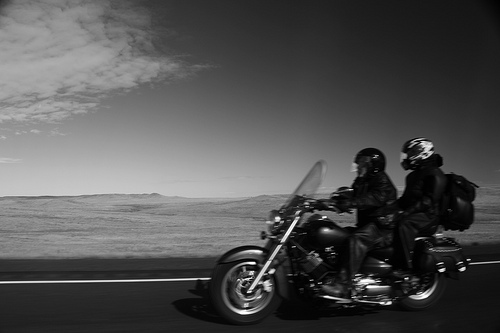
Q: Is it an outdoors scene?
A: Yes, it is outdoors.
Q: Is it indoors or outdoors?
A: It is outdoors.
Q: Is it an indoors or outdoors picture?
A: It is outdoors.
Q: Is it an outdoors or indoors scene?
A: It is outdoors.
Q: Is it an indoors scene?
A: No, it is outdoors.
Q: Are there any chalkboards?
A: No, there are no chalkboards.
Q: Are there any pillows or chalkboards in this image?
A: No, there are no chalkboards or pillows.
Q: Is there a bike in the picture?
A: Yes, there is a bike.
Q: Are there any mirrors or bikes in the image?
A: Yes, there is a bike.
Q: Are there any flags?
A: No, there are no flags.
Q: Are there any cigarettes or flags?
A: No, there are no flags or cigarettes.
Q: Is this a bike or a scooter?
A: This is a bike.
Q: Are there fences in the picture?
A: No, there are no fences.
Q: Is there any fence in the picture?
A: No, there are no fences.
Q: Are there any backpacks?
A: Yes, there is a backpack.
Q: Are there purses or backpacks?
A: Yes, there is a backpack.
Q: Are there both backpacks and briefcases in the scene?
A: No, there is a backpack but no briefcases.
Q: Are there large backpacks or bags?
A: Yes, there is a large backpack.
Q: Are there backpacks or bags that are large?
A: Yes, the backpack is large.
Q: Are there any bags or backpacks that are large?
A: Yes, the backpack is large.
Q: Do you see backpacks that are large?
A: Yes, there is a large backpack.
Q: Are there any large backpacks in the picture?
A: Yes, there is a large backpack.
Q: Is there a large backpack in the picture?
A: Yes, there is a large backpack.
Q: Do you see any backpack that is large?
A: Yes, there is a backpack that is large.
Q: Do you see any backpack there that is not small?
A: Yes, there is a large backpack.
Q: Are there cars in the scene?
A: No, there are no cars.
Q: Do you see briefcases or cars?
A: No, there are no cars or briefcases.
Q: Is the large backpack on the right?
A: Yes, the backpack is on the right of the image.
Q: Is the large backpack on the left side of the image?
A: No, the backpack is on the right of the image.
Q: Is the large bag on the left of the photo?
A: No, the backpack is on the right of the image.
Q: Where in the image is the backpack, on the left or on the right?
A: The backpack is on the right of the image.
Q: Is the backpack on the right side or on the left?
A: The backpack is on the right of the image.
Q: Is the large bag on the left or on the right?
A: The backpack is on the right of the image.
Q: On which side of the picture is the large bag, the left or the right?
A: The backpack is on the right of the image.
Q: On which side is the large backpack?
A: The backpack is on the right of the image.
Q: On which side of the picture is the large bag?
A: The backpack is on the right of the image.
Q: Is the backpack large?
A: Yes, the backpack is large.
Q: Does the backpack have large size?
A: Yes, the backpack is large.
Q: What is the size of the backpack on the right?
A: The backpack is large.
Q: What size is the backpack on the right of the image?
A: The backpack is large.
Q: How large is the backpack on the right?
A: The backpack is large.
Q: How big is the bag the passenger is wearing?
A: The backpack is large.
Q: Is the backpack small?
A: No, the backpack is large.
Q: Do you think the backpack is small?
A: No, the backpack is large.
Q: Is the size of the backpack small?
A: No, the backpack is large.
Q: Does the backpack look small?
A: No, the backpack is large.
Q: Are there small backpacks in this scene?
A: No, there is a backpack but it is large.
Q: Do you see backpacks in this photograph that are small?
A: No, there is a backpack but it is large.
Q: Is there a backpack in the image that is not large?
A: No, there is a backpack but it is large.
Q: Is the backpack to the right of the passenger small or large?
A: The backpack is large.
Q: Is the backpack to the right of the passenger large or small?
A: The backpack is large.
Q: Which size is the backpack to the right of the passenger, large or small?
A: The backpack is large.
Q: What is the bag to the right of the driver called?
A: The bag is a backpack.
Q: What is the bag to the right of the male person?
A: The bag is a backpack.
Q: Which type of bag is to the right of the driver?
A: The bag is a backpack.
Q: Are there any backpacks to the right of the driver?
A: Yes, there is a backpack to the right of the driver.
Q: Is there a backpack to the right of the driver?
A: Yes, there is a backpack to the right of the driver.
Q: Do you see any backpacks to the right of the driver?
A: Yes, there is a backpack to the right of the driver.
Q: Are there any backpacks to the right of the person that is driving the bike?
A: Yes, there is a backpack to the right of the driver.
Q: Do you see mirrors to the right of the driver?
A: No, there is a backpack to the right of the driver.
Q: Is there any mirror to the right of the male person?
A: No, there is a backpack to the right of the driver.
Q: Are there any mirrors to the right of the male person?
A: No, there is a backpack to the right of the driver.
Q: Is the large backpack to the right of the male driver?
A: Yes, the backpack is to the right of the driver.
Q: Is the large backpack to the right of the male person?
A: Yes, the backpack is to the right of the driver.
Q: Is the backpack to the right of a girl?
A: No, the backpack is to the right of the driver.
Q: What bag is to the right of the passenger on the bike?
A: The bag is a backpack.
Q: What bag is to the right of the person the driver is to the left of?
A: The bag is a backpack.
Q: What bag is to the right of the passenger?
A: The bag is a backpack.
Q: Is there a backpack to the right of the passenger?
A: Yes, there is a backpack to the right of the passenger.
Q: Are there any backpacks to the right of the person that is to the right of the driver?
A: Yes, there is a backpack to the right of the passenger.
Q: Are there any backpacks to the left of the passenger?
A: No, the backpack is to the right of the passenger.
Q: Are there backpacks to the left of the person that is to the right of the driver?
A: No, the backpack is to the right of the passenger.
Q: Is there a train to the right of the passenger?
A: No, there is a backpack to the right of the passenger.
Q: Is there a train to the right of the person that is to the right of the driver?
A: No, there is a backpack to the right of the passenger.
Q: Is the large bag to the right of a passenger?
A: Yes, the backpack is to the right of a passenger.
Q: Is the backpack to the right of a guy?
A: No, the backpack is to the right of a passenger.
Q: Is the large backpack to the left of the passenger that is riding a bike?
A: No, the backpack is to the right of the passenger.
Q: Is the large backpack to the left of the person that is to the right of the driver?
A: No, the backpack is to the right of the passenger.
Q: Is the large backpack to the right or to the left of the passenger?
A: The backpack is to the right of the passenger.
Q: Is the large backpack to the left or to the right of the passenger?
A: The backpack is to the right of the passenger.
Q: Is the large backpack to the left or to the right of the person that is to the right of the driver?
A: The backpack is to the right of the passenger.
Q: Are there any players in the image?
A: No, there are no players.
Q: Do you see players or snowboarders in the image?
A: No, there are no players or snowboarders.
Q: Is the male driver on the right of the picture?
A: Yes, the driver is on the right of the image.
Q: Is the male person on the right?
A: Yes, the driver is on the right of the image.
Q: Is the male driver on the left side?
A: No, the driver is on the right of the image.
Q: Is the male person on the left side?
A: No, the driver is on the right of the image.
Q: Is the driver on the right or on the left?
A: The driver is on the right of the image.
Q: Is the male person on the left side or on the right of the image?
A: The driver is on the right of the image.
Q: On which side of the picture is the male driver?
A: The driver is on the right of the image.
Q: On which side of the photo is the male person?
A: The driver is on the right of the image.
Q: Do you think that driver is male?
A: Yes, the driver is male.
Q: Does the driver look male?
A: Yes, the driver is male.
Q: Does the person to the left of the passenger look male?
A: Yes, the driver is male.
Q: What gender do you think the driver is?
A: The driver is male.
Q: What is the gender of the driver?
A: The driver is male.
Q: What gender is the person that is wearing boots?
A: The driver is male.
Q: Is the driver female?
A: No, the driver is male.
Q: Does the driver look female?
A: No, the driver is male.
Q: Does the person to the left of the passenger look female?
A: No, the driver is male.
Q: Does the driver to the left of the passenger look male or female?
A: The driver is male.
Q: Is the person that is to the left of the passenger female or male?
A: The driver is male.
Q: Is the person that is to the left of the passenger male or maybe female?
A: The driver is male.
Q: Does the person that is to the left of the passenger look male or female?
A: The driver is male.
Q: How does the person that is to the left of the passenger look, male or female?
A: The driver is male.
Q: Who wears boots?
A: The driver wears boots.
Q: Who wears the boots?
A: The driver wears boots.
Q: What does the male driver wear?
A: The driver wears boots.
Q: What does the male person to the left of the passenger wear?
A: The driver wears boots.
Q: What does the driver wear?
A: The driver wears boots.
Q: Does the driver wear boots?
A: Yes, the driver wears boots.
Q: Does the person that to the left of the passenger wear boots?
A: Yes, the driver wears boots.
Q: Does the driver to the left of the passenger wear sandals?
A: No, the driver wears boots.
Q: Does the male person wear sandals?
A: No, the driver wears boots.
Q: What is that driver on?
A: The driver is on the bike.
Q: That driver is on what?
A: The driver is on the bike.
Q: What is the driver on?
A: The driver is on the bike.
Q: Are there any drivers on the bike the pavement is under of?
A: Yes, there is a driver on the bike.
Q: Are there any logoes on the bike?
A: No, there is a driver on the bike.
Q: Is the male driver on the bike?
A: Yes, the driver is on the bike.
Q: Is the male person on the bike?
A: Yes, the driver is on the bike.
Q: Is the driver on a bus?
A: No, the driver is on the bike.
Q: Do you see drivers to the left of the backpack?
A: Yes, there is a driver to the left of the backpack.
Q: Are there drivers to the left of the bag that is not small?
A: Yes, there is a driver to the left of the backpack.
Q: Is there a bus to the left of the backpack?
A: No, there is a driver to the left of the backpack.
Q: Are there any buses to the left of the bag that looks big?
A: No, there is a driver to the left of the backpack.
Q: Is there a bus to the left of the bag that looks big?
A: No, there is a driver to the left of the backpack.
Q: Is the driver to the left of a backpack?
A: Yes, the driver is to the left of a backpack.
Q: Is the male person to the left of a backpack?
A: Yes, the driver is to the left of a backpack.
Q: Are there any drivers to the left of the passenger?
A: Yes, there is a driver to the left of the passenger.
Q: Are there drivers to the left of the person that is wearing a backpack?
A: Yes, there is a driver to the left of the passenger.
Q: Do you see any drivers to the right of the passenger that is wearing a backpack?
A: No, the driver is to the left of the passenger.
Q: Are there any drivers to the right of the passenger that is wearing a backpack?
A: No, the driver is to the left of the passenger.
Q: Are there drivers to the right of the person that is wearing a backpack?
A: No, the driver is to the left of the passenger.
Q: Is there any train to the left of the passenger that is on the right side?
A: No, there is a driver to the left of the passenger.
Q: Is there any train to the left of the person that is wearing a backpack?
A: No, there is a driver to the left of the passenger.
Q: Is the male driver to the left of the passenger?
A: Yes, the driver is to the left of the passenger.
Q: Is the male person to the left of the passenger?
A: Yes, the driver is to the left of the passenger.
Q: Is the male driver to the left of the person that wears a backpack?
A: Yes, the driver is to the left of the passenger.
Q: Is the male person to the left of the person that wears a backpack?
A: Yes, the driver is to the left of the passenger.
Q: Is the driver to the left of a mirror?
A: No, the driver is to the left of the passenger.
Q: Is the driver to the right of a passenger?
A: No, the driver is to the left of a passenger.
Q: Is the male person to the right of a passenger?
A: No, the driver is to the left of a passenger.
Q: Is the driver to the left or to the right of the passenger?
A: The driver is to the left of the passenger.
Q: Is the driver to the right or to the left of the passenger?
A: The driver is to the left of the passenger.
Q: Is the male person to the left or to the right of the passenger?
A: The driver is to the left of the passenger.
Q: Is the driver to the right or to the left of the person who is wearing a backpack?
A: The driver is to the left of the passenger.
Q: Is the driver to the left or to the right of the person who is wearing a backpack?
A: The driver is to the left of the passenger.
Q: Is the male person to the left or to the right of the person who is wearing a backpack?
A: The driver is to the left of the passenger.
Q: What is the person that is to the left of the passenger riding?
A: The driver is riding a bike.